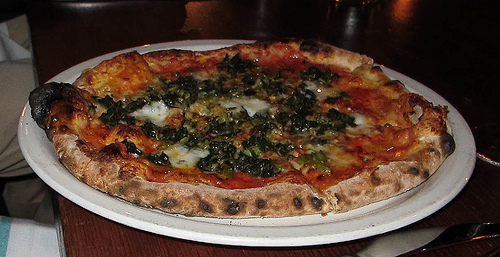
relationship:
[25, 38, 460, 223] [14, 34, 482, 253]
pizza on dish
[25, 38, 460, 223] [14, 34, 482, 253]
pizza sitting on plate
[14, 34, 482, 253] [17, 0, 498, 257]
dish on table